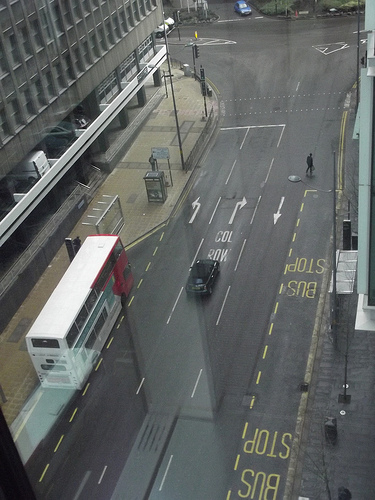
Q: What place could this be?
A: It is a street.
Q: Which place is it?
A: It is a street.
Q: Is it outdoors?
A: Yes, it is outdoors.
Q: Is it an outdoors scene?
A: Yes, it is outdoors.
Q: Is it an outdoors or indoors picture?
A: It is outdoors.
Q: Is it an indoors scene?
A: No, it is outdoors.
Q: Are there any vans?
A: No, there are no vans.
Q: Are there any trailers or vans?
A: No, there are no vans or trailers.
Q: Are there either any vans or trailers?
A: No, there are no vans or trailers.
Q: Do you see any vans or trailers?
A: No, there are no vans or trailers.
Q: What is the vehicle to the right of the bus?
A: The vehicle is a car.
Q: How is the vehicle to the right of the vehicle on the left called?
A: The vehicle is a car.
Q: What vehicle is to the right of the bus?
A: The vehicle is a car.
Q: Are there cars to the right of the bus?
A: Yes, there is a car to the right of the bus.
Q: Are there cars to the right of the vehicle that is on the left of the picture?
A: Yes, there is a car to the right of the bus.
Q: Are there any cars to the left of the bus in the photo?
A: No, the car is to the right of the bus.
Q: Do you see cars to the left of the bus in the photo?
A: No, the car is to the right of the bus.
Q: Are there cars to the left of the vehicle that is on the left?
A: No, the car is to the right of the bus.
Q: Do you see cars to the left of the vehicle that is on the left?
A: No, the car is to the right of the bus.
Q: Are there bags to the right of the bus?
A: No, there is a car to the right of the bus.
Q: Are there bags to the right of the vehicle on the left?
A: No, there is a car to the right of the bus.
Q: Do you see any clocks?
A: No, there are no clocks.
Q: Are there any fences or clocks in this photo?
A: No, there are no clocks or fences.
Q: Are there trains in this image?
A: No, there are no trains.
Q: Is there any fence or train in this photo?
A: No, there are no trains or fences.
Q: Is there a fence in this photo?
A: No, there are no fences.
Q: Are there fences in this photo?
A: No, there are no fences.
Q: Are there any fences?
A: No, there are no fences.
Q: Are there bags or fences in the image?
A: No, there are no fences or bags.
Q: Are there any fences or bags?
A: No, there are no fences or bags.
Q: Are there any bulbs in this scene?
A: No, there are no bulbs.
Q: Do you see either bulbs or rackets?
A: No, there are no bulbs or rackets.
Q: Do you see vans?
A: No, there are no vans.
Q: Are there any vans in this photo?
A: No, there are no vans.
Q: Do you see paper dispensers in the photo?
A: No, there are no paper dispensers.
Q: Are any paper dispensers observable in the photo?
A: No, there are no paper dispensers.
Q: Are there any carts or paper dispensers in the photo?
A: No, there are no paper dispensers or carts.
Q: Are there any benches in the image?
A: No, there are no benches.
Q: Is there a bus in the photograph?
A: Yes, there is a bus.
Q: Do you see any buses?
A: Yes, there is a bus.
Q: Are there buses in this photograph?
A: Yes, there is a bus.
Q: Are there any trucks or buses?
A: Yes, there is a bus.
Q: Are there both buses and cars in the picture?
A: Yes, there are both a bus and a car.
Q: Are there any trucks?
A: No, there are no trucks.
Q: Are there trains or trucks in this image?
A: No, there are no trucks or trains.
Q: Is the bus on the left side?
A: Yes, the bus is on the left of the image.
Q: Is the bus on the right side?
A: No, the bus is on the left of the image.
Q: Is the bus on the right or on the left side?
A: The bus is on the left of the image.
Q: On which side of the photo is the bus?
A: The bus is on the left of the image.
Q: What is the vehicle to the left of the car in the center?
A: The vehicle is a bus.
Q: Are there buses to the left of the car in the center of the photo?
A: Yes, there is a bus to the left of the car.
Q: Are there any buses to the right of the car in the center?
A: No, the bus is to the left of the car.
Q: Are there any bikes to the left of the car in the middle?
A: No, there is a bus to the left of the car.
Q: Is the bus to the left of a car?
A: Yes, the bus is to the left of a car.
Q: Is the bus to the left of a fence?
A: No, the bus is to the left of a car.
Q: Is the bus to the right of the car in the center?
A: No, the bus is to the left of the car.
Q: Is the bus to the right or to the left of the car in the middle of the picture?
A: The bus is to the left of the car.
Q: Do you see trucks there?
A: No, there are no trucks.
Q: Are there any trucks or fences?
A: No, there are no trucks or fences.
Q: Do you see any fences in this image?
A: No, there are no fences.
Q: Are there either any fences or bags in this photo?
A: No, there are no fences or bags.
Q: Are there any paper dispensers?
A: No, there are no paper dispensers.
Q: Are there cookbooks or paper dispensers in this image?
A: No, there are no paper dispensers or cookbooks.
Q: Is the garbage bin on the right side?
A: Yes, the garbage bin is on the right of the image.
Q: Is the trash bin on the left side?
A: No, the trash bin is on the right of the image.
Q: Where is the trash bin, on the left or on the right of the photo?
A: The trash bin is on the right of the image.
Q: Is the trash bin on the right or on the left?
A: The trash bin is on the right of the image.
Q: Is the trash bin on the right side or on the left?
A: The trash bin is on the right of the image.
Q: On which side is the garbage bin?
A: The garbage bin is on the right of the image.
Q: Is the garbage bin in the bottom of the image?
A: Yes, the garbage bin is in the bottom of the image.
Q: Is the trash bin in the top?
A: No, the trash bin is in the bottom of the image.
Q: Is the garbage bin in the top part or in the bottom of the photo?
A: The garbage bin is in the bottom of the image.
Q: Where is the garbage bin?
A: The garbage bin is on the sidewalk.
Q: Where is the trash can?
A: The garbage bin is on the sidewalk.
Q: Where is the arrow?
A: The arrow is on the road.